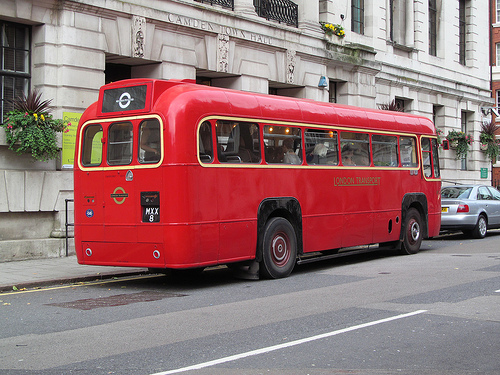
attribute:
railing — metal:
[255, 0, 290, 25]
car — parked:
[431, 189, 499, 247]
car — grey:
[438, 181, 498, 241]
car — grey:
[435, 182, 498, 233]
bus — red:
[70, 70, 442, 283]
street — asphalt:
[2, 286, 499, 365]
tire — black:
[258, 216, 299, 279]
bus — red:
[46, 51, 493, 333]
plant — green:
[5, 91, 69, 160]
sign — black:
[80, 76, 223, 138]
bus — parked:
[64, 77, 451, 259]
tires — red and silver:
[401, 206, 428, 254]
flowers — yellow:
[321, 21, 346, 38]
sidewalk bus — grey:
[64, 80, 170, 282]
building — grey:
[2, 0, 494, 234]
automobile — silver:
[439, 177, 499, 243]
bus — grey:
[88, 68, 370, 275]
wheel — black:
[248, 212, 301, 279]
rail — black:
[57, 158, 86, 307]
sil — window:
[0, 121, 66, 217]